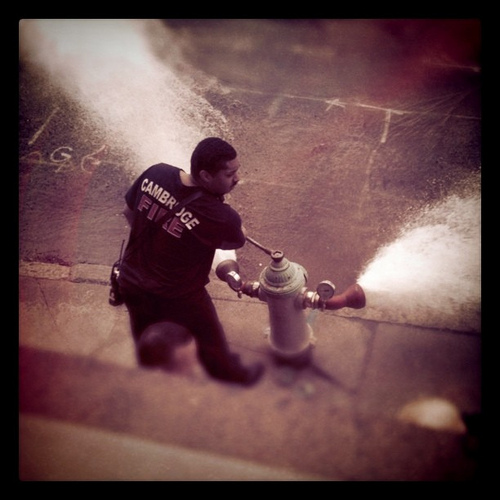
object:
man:
[101, 134, 273, 392]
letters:
[136, 193, 153, 213]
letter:
[46, 143, 77, 177]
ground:
[17, 30, 130, 253]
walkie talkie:
[106, 235, 127, 309]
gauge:
[315, 278, 337, 301]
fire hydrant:
[212, 238, 370, 373]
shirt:
[115, 161, 248, 302]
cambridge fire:
[133, 174, 201, 241]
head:
[393, 390, 468, 436]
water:
[354, 161, 482, 338]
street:
[276, 21, 479, 254]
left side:
[432, 8, 476, 474]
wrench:
[244, 230, 284, 263]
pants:
[112, 264, 253, 391]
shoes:
[217, 358, 270, 394]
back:
[116, 161, 248, 296]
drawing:
[19, 103, 110, 183]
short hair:
[188, 133, 239, 182]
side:
[112, 173, 148, 329]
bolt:
[270, 247, 287, 264]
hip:
[108, 273, 210, 319]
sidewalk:
[23, 253, 477, 473]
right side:
[429, 17, 476, 478]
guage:
[224, 268, 244, 291]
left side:
[24, 21, 68, 476]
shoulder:
[194, 191, 245, 241]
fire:
[133, 192, 187, 239]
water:
[16, 17, 250, 277]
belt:
[115, 273, 206, 297]